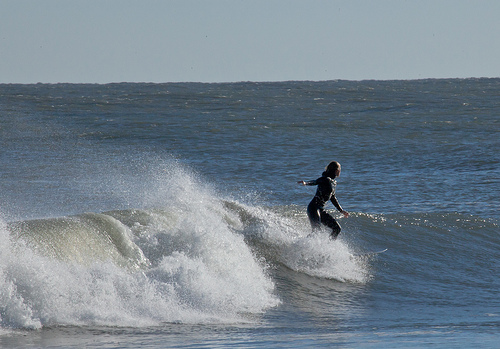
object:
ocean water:
[1, 77, 499, 347]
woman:
[297, 161, 351, 244]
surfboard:
[346, 247, 388, 255]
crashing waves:
[0, 192, 373, 348]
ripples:
[289, 203, 499, 230]